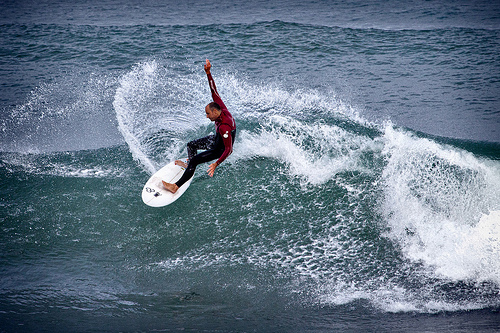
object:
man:
[161, 57, 237, 194]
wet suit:
[176, 74, 235, 186]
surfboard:
[139, 157, 196, 208]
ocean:
[0, 1, 499, 331]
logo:
[221, 129, 229, 140]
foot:
[174, 155, 186, 171]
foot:
[161, 179, 180, 193]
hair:
[209, 102, 221, 111]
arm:
[202, 57, 226, 108]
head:
[205, 102, 222, 122]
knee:
[186, 141, 197, 152]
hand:
[204, 162, 219, 177]